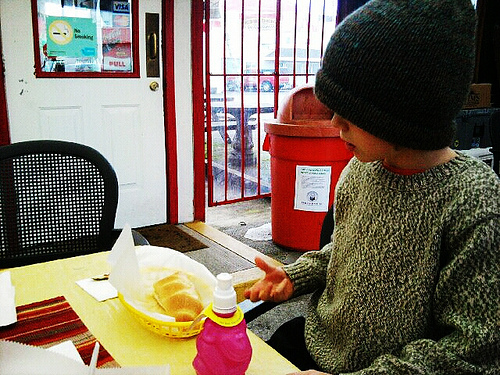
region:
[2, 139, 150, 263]
a black chair with mesh backing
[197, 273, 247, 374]
a pink bottle with white squirt top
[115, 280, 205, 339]
a plastic yellow food basket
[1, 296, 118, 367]
a multicolored striped place mat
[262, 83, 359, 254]
a red trashcan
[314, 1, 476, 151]
a toboggan, dark in color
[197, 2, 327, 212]
a red metal framed gate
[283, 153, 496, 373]
a thick grey sweater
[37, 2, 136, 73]
stickers posted on window of door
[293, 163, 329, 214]
white label on red trashcan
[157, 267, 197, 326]
bread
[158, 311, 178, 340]
a yellow basket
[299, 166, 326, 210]
white sign on the trash can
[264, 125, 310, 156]
a red trash can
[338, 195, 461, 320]
boy is wearing a sweater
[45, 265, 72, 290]
a table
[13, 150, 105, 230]
a black chair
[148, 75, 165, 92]
a lock on the door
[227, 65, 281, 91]
a red truck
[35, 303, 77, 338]
a place mat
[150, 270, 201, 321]
bread in a basket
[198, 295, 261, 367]
a pink container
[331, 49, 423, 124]
a black hat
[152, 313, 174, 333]
yellow basket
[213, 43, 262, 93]
a red gate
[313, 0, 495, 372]
Small child sitting in a chair.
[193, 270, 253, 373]
Childs pink and white sippy cup.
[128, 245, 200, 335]
Food basket with partially eaten food.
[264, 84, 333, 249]
Red trasshcan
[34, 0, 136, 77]
Door window with papers and stickers on it.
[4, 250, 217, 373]
Table with food, cup and other items.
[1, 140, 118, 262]
Black chair with a woven back.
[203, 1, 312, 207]
Red bars on a door.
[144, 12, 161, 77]
Brass door handle.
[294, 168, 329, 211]
White label on red trashcan.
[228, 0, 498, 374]
a child sitting at a table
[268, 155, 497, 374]
a gray wool sweater on the child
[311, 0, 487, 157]
a dark gray wool hat on the child's head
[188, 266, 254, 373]
a pink squeeze bottle holding a drink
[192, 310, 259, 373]
a squeeze bottle in the form of a chimpanzee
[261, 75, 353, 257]
a dirty red trash can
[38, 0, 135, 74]
signs on the window of the door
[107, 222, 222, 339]
a sandwich in a yellow food basket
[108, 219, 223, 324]
a paper wrapper underneath the sandwich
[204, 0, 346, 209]
red iron bars near the door